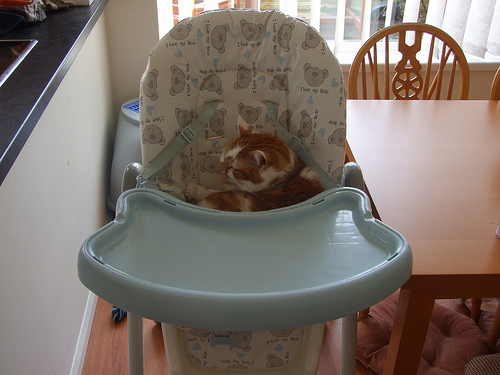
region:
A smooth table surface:
[381, 124, 476, 234]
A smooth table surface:
[444, 98, 499, 154]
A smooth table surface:
[356, 97, 404, 158]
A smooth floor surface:
[142, 345, 172, 372]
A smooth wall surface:
[51, 115, 93, 212]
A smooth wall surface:
[2, 181, 69, 333]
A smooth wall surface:
[110, 9, 149, 72]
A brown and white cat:
[217, 134, 319, 204]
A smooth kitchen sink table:
[8, 72, 53, 108]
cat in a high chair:
[103, 15, 378, 368]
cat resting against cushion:
[181, 128, 322, 219]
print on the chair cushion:
[202, 25, 289, 87]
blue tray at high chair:
[78, 182, 398, 302]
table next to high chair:
[339, 93, 497, 364]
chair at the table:
[343, 17, 480, 113]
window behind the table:
[165, 2, 496, 54]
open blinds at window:
[170, 1, 496, 43]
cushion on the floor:
[360, 292, 475, 362]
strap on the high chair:
[132, 109, 223, 160]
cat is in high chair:
[178, 128, 310, 238]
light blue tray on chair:
[60, 173, 402, 323]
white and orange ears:
[221, 111, 283, 181]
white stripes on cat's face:
[220, 135, 247, 199]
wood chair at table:
[347, 45, 475, 103]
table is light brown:
[342, 104, 496, 299]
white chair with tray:
[140, 21, 388, 198]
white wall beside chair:
[22, 47, 150, 344]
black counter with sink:
[1, 20, 85, 182]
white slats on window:
[170, 1, 495, 52]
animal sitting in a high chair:
[84, 8, 421, 366]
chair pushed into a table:
[337, 21, 482, 123]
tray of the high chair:
[78, 173, 415, 330]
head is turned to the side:
[212, 129, 304, 195]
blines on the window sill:
[161, 2, 499, 57]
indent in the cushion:
[437, 321, 456, 338]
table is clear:
[340, 96, 499, 278]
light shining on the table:
[347, 106, 402, 156]